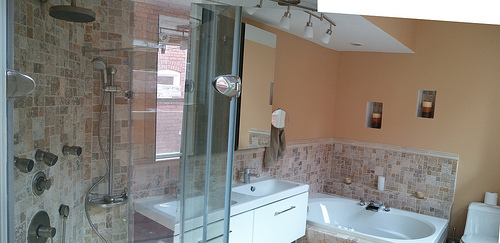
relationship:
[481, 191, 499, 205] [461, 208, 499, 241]
toilet paper on back of toilet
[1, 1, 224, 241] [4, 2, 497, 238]
shower in bathroom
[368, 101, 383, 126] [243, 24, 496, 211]
hole in wall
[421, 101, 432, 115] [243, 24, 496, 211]
candle on wall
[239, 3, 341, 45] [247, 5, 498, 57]
lights on ceiling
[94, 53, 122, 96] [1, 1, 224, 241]
shower head in shower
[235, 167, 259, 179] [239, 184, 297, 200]
faucet on sink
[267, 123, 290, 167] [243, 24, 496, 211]
towel on wall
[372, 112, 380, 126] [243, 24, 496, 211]
candle on wall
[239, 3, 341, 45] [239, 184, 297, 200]
lights above sink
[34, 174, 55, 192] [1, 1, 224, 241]
knob on shower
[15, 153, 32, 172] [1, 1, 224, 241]
knob on shower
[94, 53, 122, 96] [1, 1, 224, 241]
shower head inside shower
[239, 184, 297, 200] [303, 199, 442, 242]
sink next to bath tub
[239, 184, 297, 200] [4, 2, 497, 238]
sink in bathroom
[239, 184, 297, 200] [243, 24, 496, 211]
sink in front of wall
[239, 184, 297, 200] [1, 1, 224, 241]
sink next to shower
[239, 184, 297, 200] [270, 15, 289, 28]
sink under light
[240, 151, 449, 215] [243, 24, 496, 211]
tiles on wall